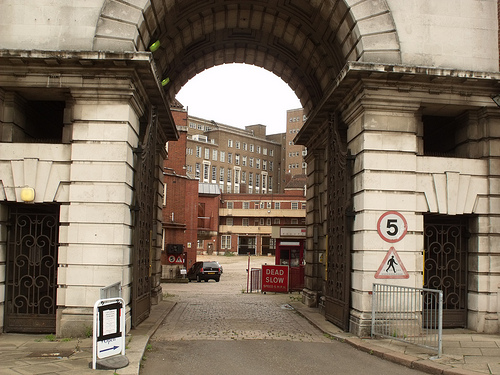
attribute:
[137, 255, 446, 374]
street — cobbleston 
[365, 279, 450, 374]
barrier — small , metal 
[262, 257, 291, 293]
sign — red , white 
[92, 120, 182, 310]
gate — brown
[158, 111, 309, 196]
building — tan , large 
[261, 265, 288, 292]
sign — red , white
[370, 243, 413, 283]
sign — triangle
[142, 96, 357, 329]
gate — open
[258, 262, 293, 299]
sign — red 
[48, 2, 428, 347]
archway — Large 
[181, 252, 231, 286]
vehicle — black 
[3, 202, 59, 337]
gate — brown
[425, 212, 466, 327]
door — iron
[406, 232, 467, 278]
gate — brown 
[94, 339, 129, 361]
arrow — black 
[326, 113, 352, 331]
gate — brown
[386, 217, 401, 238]
number 5 — black 